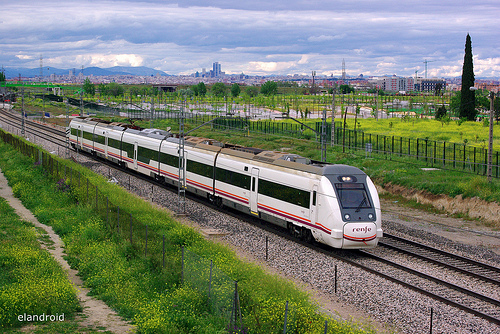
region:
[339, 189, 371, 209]
A train windscreen in the photo.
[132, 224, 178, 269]
A mesh wire fence.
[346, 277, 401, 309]
Track ballast in the picture.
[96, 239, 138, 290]
Green plants in the photo.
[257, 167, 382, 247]
A train in the photo.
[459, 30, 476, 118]
A tree in the photo.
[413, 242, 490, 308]
A rail line in the photo.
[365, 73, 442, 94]
Buildings in the photo.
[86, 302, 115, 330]
A dirt road in the photo.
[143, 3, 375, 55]
Cloudy skies in the photo.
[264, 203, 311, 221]
red and pink stripes on the side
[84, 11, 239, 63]
thick white clouds overhead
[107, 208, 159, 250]
a metal chain link fence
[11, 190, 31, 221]
a dirt path between the grass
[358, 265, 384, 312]
gray gravel scattered on the ground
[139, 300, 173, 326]
yellow flowers on the bushes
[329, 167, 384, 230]
flat front on the train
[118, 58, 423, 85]
a city in the background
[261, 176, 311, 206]
long rectangular window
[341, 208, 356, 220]
a round white headlight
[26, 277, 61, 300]
weeds on the ground.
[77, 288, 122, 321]
path near the weeds.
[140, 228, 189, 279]
fence in the weeds.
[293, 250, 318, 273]
pebbles near the tracks.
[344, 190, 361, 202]
windshield on the train.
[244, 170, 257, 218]
door on the train.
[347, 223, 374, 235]
word on the train.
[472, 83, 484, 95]
light on the pole.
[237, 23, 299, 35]
clouds in the sky.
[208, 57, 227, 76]
tall buildings in the background.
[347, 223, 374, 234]
'renfe' on a train in spain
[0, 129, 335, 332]
some sort of wrought iron fence amid greenery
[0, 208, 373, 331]
green plants w/ yellow flowers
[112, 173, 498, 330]
black stones along the railway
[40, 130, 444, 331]
little black poles along the railway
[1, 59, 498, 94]
on the horizon, a city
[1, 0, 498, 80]
lavender storm clouds rolling in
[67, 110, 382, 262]
a white train on the train tracks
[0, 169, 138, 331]
trail through the grass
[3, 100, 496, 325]
train tracks in the rocks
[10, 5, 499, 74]
gray clouds in the sky above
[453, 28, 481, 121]
a tall skinny tree on the side of the road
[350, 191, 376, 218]
windshield wipers on the train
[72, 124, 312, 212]
windows on the train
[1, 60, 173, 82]
a mountain range behind the train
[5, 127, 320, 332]
fence lining the tracks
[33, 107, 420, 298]
a train on the tracks